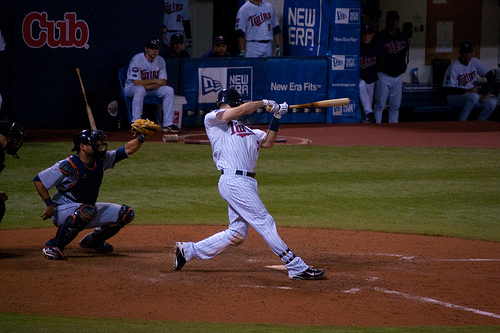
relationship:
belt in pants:
[221, 169, 257, 179] [172, 170, 327, 282]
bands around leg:
[275, 244, 298, 262] [181, 219, 249, 261]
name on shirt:
[228, 119, 254, 138] [200, 105, 266, 178]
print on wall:
[20, 10, 91, 51] [0, 0, 130, 128]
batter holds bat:
[170, 87, 326, 282] [282, 93, 348, 116]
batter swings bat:
[172, 88, 325, 280] [287, 96, 351, 118]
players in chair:
[119, 35, 184, 135] [116, 65, 164, 128]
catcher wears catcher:
[32, 116, 167, 259] [30, 117, 164, 263]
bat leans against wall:
[72, 66, 101, 141] [1, 0, 129, 129]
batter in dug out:
[170, 87, 326, 282] [18, 0, 495, 169]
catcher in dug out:
[30, 117, 164, 263] [18, 0, 495, 169]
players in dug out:
[116, 26, 186, 143] [18, 0, 495, 169]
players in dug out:
[364, 13, 406, 140] [18, 0, 495, 169]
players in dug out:
[443, 36, 496, 138] [18, 0, 495, 169]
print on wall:
[18, 2, 100, 49] [30, 12, 122, 111]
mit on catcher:
[126, 105, 175, 137] [43, 117, 143, 248]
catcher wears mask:
[30, 117, 164, 263] [70, 123, 106, 163]